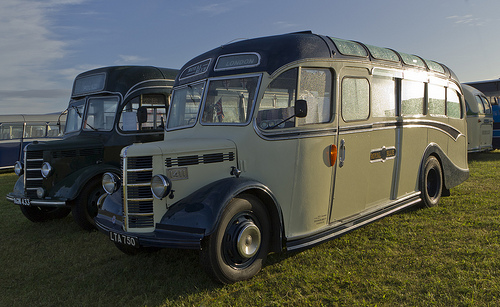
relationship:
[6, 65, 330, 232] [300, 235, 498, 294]
black vehicle parked on field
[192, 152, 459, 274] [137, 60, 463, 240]
wheels on vehicle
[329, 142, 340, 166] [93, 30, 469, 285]
light on bus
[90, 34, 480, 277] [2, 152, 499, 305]
bus in grass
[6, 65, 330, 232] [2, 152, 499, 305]
black vehicle in grass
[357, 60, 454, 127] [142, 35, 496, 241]
shining on bus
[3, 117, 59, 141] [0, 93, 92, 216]
area behind bus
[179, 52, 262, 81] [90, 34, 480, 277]
sign on bus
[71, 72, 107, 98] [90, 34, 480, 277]
sign on bus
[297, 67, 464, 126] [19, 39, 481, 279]
passenger window on buses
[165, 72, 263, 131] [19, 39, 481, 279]
window on buses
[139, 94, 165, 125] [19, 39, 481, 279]
window on buses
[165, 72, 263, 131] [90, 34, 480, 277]
window on bus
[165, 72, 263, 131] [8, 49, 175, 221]
window on bus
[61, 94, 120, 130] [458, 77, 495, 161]
windshield on bus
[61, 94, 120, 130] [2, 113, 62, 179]
windshield on bus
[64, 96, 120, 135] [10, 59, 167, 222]
windshield on bus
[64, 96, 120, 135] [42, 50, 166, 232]
windshield on bus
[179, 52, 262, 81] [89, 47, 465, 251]
sign on bus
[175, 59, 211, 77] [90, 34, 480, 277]
sign on bus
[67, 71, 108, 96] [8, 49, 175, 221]
sign on bus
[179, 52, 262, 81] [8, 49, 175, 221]
sign on bus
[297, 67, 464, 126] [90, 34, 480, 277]
passenger window on bus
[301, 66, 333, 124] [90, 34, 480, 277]
passenger window on bus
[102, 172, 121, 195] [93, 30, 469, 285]
headlight on bus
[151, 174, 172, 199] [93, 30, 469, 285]
car lights on bus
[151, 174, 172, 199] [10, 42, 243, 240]
car lights on car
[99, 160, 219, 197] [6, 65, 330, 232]
headlight on black vehicle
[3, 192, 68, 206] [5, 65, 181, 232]
front fender on car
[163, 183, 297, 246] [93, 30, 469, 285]
fender on bus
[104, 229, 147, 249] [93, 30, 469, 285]
license on bus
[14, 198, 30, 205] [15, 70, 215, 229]
license plates on car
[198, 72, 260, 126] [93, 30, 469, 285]
window on bus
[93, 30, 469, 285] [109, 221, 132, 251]
bus have license plates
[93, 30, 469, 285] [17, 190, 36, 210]
bus have license plates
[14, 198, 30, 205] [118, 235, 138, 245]
license plates have numbers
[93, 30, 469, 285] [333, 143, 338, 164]
bus has light